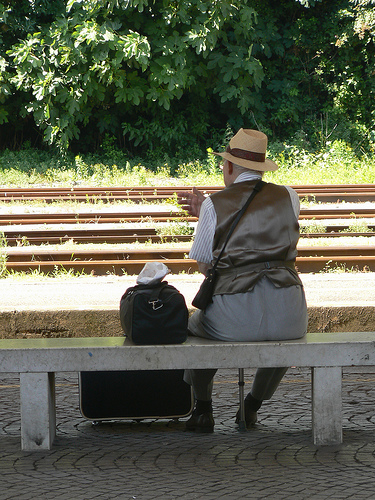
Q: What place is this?
A: It is a walkway.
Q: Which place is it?
A: It is a walkway.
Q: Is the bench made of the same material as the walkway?
A: Yes, both the bench and the walkway are made of concrete.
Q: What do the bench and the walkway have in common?
A: The material, both the bench and the walkway are concrete.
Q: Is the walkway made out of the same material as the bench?
A: Yes, both the walkway and the bench are made of concrete.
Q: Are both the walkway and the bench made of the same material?
A: Yes, both the walkway and the bench are made of concrete.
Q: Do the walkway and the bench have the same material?
A: Yes, both the walkway and the bench are made of concrete.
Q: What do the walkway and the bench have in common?
A: The material, both the walkway and the bench are concrete.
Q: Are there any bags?
A: Yes, there is a bag.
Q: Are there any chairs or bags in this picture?
A: Yes, there is a bag.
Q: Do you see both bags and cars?
A: No, there is a bag but no cars.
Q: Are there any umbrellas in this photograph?
A: No, there are no umbrellas.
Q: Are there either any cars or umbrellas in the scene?
A: No, there are no umbrellas or cars.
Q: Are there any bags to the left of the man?
A: Yes, there is a bag to the left of the man.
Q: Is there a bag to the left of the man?
A: Yes, there is a bag to the left of the man.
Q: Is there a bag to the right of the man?
A: No, the bag is to the left of the man.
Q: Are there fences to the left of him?
A: No, there is a bag to the left of the man.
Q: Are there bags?
A: Yes, there is a bag.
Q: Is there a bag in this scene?
A: Yes, there is a bag.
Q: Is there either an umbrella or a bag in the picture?
A: Yes, there is a bag.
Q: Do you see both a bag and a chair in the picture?
A: No, there is a bag but no chairs.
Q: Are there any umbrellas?
A: No, there are no umbrellas.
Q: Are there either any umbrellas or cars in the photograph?
A: No, there are no umbrellas or cars.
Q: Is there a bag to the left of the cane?
A: Yes, there is a bag to the left of the cane.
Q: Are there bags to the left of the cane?
A: Yes, there is a bag to the left of the cane.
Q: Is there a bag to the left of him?
A: Yes, there is a bag to the left of the man.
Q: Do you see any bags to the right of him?
A: No, the bag is to the left of the man.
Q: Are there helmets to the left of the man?
A: No, there is a bag to the left of the man.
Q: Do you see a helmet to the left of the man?
A: No, there is a bag to the left of the man.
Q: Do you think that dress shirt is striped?
A: Yes, the dress shirt is striped.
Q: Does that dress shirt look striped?
A: Yes, the dress shirt is striped.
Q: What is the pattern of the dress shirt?
A: The dress shirt is striped.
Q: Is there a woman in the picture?
A: No, there are no women.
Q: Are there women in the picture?
A: No, there are no women.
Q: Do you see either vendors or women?
A: No, there are no women or vendors.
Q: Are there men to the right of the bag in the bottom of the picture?
A: Yes, there is a man to the right of the bag.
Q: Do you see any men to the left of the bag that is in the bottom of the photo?
A: No, the man is to the right of the bag.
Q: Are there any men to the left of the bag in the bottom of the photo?
A: No, the man is to the right of the bag.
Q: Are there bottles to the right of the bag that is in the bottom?
A: No, there is a man to the right of the bag.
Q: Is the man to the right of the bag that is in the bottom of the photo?
A: Yes, the man is to the right of the bag.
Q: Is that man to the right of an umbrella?
A: No, the man is to the right of the bag.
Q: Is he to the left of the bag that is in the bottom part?
A: No, the man is to the right of the bag.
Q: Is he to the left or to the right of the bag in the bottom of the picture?
A: The man is to the right of the bag.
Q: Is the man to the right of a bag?
A: Yes, the man is to the right of a bag.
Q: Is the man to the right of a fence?
A: No, the man is to the right of a bag.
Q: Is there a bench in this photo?
A: Yes, there is a bench.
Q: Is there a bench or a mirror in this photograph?
A: Yes, there is a bench.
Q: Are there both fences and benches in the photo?
A: No, there is a bench but no fences.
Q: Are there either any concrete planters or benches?
A: Yes, there is a concrete bench.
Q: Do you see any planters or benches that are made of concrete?
A: Yes, the bench is made of concrete.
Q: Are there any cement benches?
A: Yes, there is a bench that is made of cement.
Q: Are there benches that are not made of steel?
A: Yes, there is a bench that is made of cement.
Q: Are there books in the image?
A: No, there are no books.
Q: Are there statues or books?
A: No, there are no books or statues.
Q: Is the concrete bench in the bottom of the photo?
A: Yes, the bench is in the bottom of the image.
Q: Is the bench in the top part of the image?
A: No, the bench is in the bottom of the image.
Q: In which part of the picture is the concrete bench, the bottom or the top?
A: The bench is in the bottom of the image.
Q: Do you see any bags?
A: Yes, there is a bag.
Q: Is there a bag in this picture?
A: Yes, there is a bag.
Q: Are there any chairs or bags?
A: Yes, there is a bag.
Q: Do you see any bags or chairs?
A: Yes, there is a bag.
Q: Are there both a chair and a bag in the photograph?
A: No, there is a bag but no chairs.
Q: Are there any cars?
A: No, there are no cars.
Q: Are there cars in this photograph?
A: No, there are no cars.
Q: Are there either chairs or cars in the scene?
A: No, there are no cars or chairs.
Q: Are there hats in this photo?
A: Yes, there is a hat.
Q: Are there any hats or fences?
A: Yes, there is a hat.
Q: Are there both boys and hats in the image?
A: No, there is a hat but no boys.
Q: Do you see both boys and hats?
A: No, there is a hat but no boys.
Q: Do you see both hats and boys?
A: No, there is a hat but no boys.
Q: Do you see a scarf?
A: No, there are no scarves.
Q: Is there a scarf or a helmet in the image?
A: No, there are no scarves or helmets.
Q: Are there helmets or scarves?
A: No, there are no scarves or helmets.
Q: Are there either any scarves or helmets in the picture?
A: No, there are no scarves or helmets.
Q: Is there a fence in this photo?
A: No, there are no fences.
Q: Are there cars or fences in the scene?
A: No, there are no fences or cars.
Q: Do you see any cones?
A: No, there are no cones.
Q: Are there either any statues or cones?
A: No, there are no cones or statues.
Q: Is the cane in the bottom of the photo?
A: Yes, the cane is in the bottom of the image.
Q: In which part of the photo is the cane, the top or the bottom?
A: The cane is in the bottom of the image.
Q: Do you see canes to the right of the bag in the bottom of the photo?
A: Yes, there is a cane to the right of the bag.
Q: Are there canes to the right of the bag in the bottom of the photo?
A: Yes, there is a cane to the right of the bag.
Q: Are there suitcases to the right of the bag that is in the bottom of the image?
A: No, there is a cane to the right of the bag.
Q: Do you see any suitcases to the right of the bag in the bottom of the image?
A: No, there is a cane to the right of the bag.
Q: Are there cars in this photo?
A: No, there are no cars.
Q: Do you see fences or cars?
A: No, there are no cars or fences.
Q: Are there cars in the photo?
A: No, there are no cars.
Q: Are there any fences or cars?
A: No, there are no cars or fences.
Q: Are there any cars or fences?
A: No, there are no cars or fences.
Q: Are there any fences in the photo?
A: No, there are no fences.